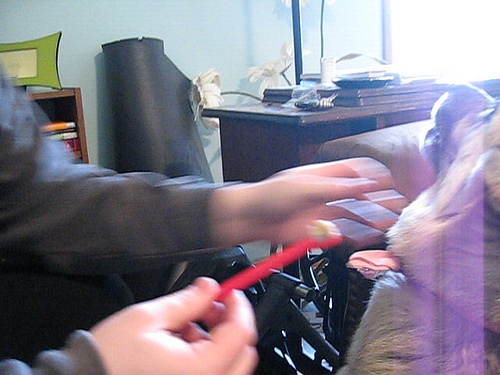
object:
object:
[215, 226, 342, 304]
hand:
[86, 277, 259, 374]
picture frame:
[4, 26, 71, 88]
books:
[47, 130, 78, 142]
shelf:
[10, 86, 91, 166]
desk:
[198, 102, 433, 181]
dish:
[328, 75, 393, 87]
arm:
[0, 63, 269, 275]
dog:
[336, 84, 499, 374]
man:
[0, 48, 406, 364]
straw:
[217, 239, 328, 312]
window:
[357, 1, 476, 71]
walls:
[170, 7, 219, 33]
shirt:
[0, 74, 237, 373]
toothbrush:
[214, 221, 342, 303]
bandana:
[310, 218, 342, 247]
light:
[318, 0, 386, 87]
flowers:
[242, 42, 295, 99]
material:
[271, 86, 293, 100]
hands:
[250, 156, 406, 246]